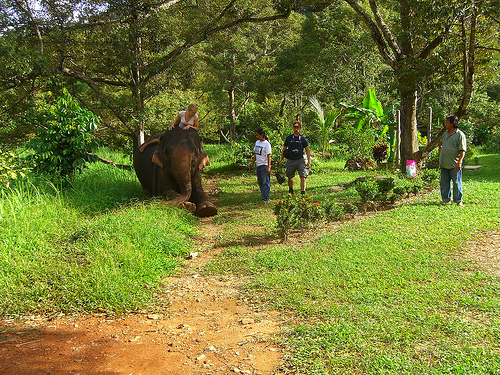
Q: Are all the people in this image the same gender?
A: No, they are both male and female.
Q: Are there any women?
A: Yes, there is a woman.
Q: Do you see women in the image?
A: Yes, there is a woman.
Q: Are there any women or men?
A: Yes, there is a woman.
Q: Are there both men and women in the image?
A: Yes, there are both a woman and a man.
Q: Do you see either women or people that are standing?
A: Yes, the woman is standing.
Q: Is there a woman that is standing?
A: Yes, there is a woman that is standing.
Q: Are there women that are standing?
A: Yes, there is a woman that is standing.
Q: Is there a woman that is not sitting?
A: Yes, there is a woman that is standing.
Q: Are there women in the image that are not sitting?
A: Yes, there is a woman that is standing.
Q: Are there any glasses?
A: No, there are no glasses.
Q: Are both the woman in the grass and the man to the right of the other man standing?
A: Yes, both the woman and the man are standing.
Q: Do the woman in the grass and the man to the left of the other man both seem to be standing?
A: Yes, both the woman and the man are standing.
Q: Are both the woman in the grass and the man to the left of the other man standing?
A: Yes, both the woman and the man are standing.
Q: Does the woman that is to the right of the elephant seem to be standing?
A: Yes, the woman is standing.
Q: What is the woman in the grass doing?
A: The woman is standing.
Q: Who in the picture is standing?
A: The woman is standing.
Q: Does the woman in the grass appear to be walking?
A: No, the woman is standing.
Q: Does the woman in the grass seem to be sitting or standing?
A: The woman is standing.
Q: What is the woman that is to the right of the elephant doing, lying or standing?
A: The woman is standing.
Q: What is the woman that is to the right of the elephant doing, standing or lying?
A: The woman is standing.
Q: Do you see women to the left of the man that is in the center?
A: Yes, there is a woman to the left of the man.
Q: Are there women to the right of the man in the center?
A: No, the woman is to the left of the man.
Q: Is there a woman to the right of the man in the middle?
A: No, the woman is to the left of the man.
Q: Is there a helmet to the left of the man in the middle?
A: No, there is a woman to the left of the man.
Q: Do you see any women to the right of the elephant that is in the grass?
A: Yes, there is a woman to the right of the elephant.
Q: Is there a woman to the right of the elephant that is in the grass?
A: Yes, there is a woman to the right of the elephant.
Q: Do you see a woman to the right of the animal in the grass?
A: Yes, there is a woman to the right of the elephant.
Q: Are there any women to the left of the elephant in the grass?
A: No, the woman is to the right of the elephant.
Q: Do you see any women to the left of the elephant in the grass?
A: No, the woman is to the right of the elephant.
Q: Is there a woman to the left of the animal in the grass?
A: No, the woman is to the right of the elephant.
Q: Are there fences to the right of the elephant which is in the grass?
A: No, there is a woman to the right of the elephant.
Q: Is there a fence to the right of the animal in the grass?
A: No, there is a woman to the right of the elephant.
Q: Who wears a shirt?
A: The woman wears a shirt.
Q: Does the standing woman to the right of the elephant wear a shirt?
A: Yes, the woman wears a shirt.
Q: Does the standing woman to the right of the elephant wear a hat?
A: No, the woman wears a shirt.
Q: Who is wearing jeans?
A: The woman is wearing jeans.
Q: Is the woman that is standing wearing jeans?
A: Yes, the woman is wearing jeans.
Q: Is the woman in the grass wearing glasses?
A: No, the woman is wearing jeans.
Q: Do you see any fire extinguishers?
A: No, there are no fire extinguishers.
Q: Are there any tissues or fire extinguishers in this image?
A: No, there are no fire extinguishers or tissues.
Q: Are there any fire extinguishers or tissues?
A: No, there are no fire extinguishers or tissues.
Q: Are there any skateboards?
A: No, there are no skateboards.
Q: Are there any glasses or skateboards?
A: No, there are no skateboards or glasses.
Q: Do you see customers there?
A: No, there are no customers.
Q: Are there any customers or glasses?
A: No, there are no customers or glasses.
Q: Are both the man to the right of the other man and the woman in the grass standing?
A: Yes, both the man and the woman are standing.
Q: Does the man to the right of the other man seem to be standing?
A: Yes, the man is standing.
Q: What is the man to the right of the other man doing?
A: The man is standing.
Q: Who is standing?
A: The man is standing.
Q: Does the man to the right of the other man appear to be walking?
A: No, the man is standing.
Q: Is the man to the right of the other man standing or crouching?
A: The man is standing.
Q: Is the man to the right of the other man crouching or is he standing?
A: The man is standing.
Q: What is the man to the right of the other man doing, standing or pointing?
A: The man is standing.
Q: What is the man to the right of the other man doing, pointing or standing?
A: The man is standing.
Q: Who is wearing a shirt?
A: The man is wearing a shirt.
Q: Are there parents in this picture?
A: No, there are no parents.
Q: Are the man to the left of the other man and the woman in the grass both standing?
A: Yes, both the man and the woman are standing.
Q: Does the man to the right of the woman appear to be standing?
A: Yes, the man is standing.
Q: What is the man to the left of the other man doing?
A: The man is standing.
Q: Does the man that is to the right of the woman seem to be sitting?
A: No, the man is standing.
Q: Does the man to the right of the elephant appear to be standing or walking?
A: The man is standing.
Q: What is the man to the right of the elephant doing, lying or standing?
A: The man is standing.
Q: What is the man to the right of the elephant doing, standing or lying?
A: The man is standing.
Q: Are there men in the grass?
A: Yes, there is a man in the grass.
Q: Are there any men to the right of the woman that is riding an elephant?
A: Yes, there is a man to the right of the woman.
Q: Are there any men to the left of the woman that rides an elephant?
A: No, the man is to the right of the woman.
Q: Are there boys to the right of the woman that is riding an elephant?
A: No, there is a man to the right of the woman.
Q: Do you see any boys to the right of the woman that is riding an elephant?
A: No, there is a man to the right of the woman.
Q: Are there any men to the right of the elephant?
A: Yes, there is a man to the right of the elephant.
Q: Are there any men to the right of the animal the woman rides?
A: Yes, there is a man to the right of the elephant.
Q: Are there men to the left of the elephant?
A: No, the man is to the right of the elephant.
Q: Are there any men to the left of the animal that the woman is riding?
A: No, the man is to the right of the elephant.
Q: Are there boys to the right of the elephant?
A: No, there is a man to the right of the elephant.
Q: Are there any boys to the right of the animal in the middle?
A: No, there is a man to the right of the elephant.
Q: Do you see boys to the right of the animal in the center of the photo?
A: No, there is a man to the right of the elephant.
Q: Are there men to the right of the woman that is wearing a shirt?
A: Yes, there is a man to the right of the woman.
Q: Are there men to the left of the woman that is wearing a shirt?
A: No, the man is to the right of the woman.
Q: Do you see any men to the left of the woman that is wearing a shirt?
A: No, the man is to the right of the woman.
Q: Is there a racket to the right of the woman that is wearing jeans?
A: No, there is a man to the right of the woman.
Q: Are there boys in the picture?
A: No, there are no boys.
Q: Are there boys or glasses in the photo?
A: No, there are no boys or glasses.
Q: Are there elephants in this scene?
A: Yes, there is an elephant.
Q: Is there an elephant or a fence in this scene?
A: Yes, there is an elephant.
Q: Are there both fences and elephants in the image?
A: No, there is an elephant but no fences.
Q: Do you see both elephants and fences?
A: No, there is an elephant but no fences.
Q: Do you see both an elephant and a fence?
A: No, there is an elephant but no fences.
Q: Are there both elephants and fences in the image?
A: No, there is an elephant but no fences.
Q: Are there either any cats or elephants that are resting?
A: Yes, the elephant is resting.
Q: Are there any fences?
A: No, there are no fences.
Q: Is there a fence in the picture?
A: No, there are no fences.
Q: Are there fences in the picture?
A: No, there are no fences.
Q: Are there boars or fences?
A: No, there are no fences or boars.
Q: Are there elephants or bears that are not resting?
A: No, there is an elephant but it is resting.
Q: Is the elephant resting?
A: Yes, the elephant is resting.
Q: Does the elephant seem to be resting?
A: Yes, the elephant is resting.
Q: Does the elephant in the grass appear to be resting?
A: Yes, the elephant is resting.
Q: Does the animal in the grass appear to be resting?
A: Yes, the elephant is resting.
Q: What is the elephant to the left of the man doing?
A: The elephant is resting.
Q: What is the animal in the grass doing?
A: The elephant is resting.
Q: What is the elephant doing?
A: The elephant is resting.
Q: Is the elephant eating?
A: No, the elephant is resting.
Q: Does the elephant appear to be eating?
A: No, the elephant is resting.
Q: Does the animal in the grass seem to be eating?
A: No, the elephant is resting.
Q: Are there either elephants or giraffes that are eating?
A: No, there is an elephant but it is resting.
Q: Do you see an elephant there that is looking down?
A: No, there is an elephant but it is resting.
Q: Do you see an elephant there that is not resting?
A: No, there is an elephant but it is resting.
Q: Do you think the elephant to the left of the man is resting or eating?
A: The elephant is resting.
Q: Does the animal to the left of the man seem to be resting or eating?
A: The elephant is resting.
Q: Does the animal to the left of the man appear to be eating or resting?
A: The elephant is resting.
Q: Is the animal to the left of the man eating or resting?
A: The elephant is resting.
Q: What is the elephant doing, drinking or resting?
A: The elephant is resting.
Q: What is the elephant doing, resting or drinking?
A: The elephant is resting.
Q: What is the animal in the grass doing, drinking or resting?
A: The elephant is resting.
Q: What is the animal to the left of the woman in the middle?
A: The animal is an elephant.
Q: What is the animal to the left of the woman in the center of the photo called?
A: The animal is an elephant.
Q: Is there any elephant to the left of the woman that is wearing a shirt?
A: Yes, there is an elephant to the left of the woman.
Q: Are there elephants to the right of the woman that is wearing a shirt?
A: No, the elephant is to the left of the woman.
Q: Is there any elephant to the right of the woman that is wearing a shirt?
A: No, the elephant is to the left of the woman.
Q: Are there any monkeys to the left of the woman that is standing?
A: No, there is an elephant to the left of the woman.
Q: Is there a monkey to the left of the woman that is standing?
A: No, there is an elephant to the left of the woman.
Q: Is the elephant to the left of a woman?
A: Yes, the elephant is to the left of a woman.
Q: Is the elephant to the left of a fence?
A: No, the elephant is to the left of a woman.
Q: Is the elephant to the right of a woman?
A: No, the elephant is to the left of a woman.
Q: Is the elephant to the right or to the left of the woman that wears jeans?
A: The elephant is to the left of the woman.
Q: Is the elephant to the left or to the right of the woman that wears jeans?
A: The elephant is to the left of the woman.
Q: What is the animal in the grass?
A: The animal is an elephant.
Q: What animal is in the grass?
A: The animal is an elephant.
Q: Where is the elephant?
A: The elephant is in the grass.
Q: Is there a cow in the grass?
A: No, there is an elephant in the grass.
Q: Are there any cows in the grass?
A: No, there is an elephant in the grass.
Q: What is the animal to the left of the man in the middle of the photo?
A: The animal is an elephant.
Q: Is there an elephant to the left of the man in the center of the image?
A: Yes, there is an elephant to the left of the man.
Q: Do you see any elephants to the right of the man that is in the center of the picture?
A: No, the elephant is to the left of the man.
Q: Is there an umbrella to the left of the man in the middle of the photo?
A: No, there is an elephant to the left of the man.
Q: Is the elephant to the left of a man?
A: Yes, the elephant is to the left of a man.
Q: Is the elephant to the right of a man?
A: No, the elephant is to the left of a man.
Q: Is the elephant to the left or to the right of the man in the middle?
A: The elephant is to the left of the man.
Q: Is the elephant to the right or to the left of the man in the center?
A: The elephant is to the left of the man.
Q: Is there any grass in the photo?
A: Yes, there is grass.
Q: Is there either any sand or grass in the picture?
A: Yes, there is grass.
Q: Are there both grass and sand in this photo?
A: No, there is grass but no sand.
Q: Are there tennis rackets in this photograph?
A: No, there are no tennis rackets.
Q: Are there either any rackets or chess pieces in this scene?
A: No, there are no rackets or chess pieces.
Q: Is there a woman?
A: Yes, there is a woman.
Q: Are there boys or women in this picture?
A: Yes, there is a woman.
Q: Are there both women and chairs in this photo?
A: No, there is a woman but no chairs.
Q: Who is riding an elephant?
A: The woman is riding an elephant.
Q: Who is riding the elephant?
A: The woman is riding an elephant.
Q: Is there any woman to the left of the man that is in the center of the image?
A: Yes, there is a woman to the left of the man.